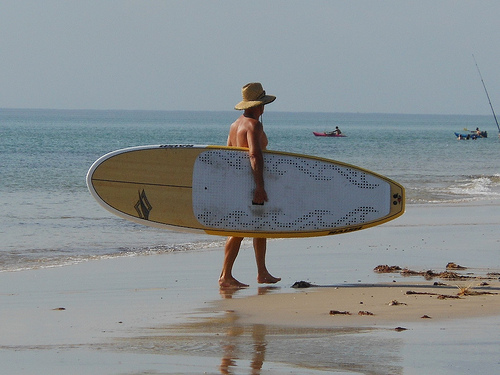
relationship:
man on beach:
[216, 82, 280, 291] [8, 189, 491, 369]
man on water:
[329, 125, 344, 137] [1, 105, 498, 270]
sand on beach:
[206, 268, 498, 324] [12, 212, 497, 370]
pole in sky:
[465, 46, 498, 121] [7, 4, 498, 111]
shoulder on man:
[242, 120, 265, 144] [216, 82, 280, 291]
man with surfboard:
[216, 82, 280, 291] [79, 136, 408, 270]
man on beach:
[216, 83, 281, 291] [30, 256, 498, 374]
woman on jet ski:
[328, 126, 343, 136] [311, 131, 346, 138]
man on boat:
[329, 125, 344, 137] [452, 125, 489, 145]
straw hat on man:
[232, 80, 278, 111] [213, 60, 284, 164]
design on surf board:
[266, 198, 387, 238] [191, 144, 394, 237]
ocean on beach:
[12, 226, 81, 275] [21, 237, 451, 372]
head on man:
[238, 77, 299, 116] [216, 82, 280, 291]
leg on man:
[251, 236, 281, 286] [216, 83, 281, 291]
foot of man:
[216, 267, 252, 292] [204, 71, 254, 233]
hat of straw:
[233, 80, 276, 112] [235, 82, 275, 110]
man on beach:
[216, 82, 280, 291] [16, 266, 177, 366]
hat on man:
[223, 74, 299, 119] [170, 57, 292, 307]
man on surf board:
[216, 82, 280, 291] [77, 134, 426, 241]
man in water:
[329, 125, 344, 137] [379, 117, 444, 174]